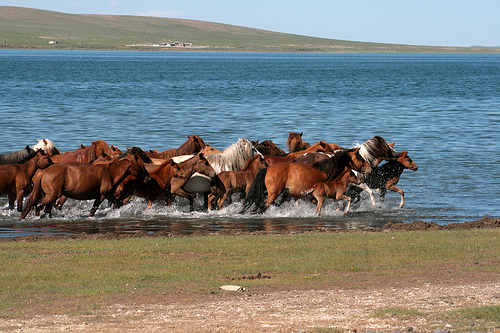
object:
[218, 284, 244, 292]
flat rock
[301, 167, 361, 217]
foal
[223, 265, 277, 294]
brown dirt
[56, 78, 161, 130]
ripples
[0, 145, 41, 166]
horses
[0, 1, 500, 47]
sky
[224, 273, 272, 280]
dung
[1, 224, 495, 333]
grass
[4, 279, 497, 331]
sand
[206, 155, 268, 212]
horse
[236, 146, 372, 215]
horse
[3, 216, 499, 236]
mud piles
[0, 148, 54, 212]
horses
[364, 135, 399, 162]
head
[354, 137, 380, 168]
mane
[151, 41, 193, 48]
building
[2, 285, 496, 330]
dirt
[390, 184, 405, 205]
horse leg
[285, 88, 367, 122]
ripples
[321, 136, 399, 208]
horse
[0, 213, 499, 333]
pathway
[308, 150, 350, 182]
mane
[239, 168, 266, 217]
tail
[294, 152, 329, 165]
horse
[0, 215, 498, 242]
dirt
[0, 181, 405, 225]
kicking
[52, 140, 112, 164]
horses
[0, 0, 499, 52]
hill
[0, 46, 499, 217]
across water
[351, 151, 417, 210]
horse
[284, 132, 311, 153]
horse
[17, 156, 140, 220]
horse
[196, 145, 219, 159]
head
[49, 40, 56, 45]
building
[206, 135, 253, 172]
white mane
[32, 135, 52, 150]
white mane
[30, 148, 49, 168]
head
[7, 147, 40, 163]
mane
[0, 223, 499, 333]
ground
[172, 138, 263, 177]
horse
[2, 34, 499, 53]
clearing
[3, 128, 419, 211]
herd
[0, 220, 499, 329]
land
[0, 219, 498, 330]
beach